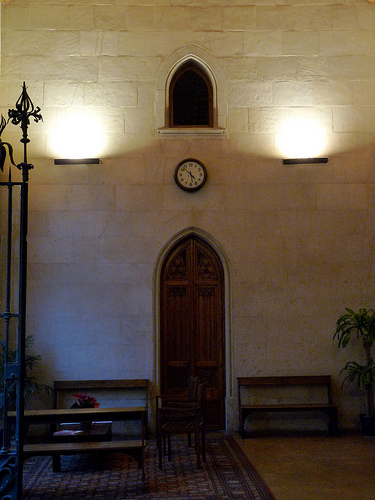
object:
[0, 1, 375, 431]
walls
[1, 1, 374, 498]
building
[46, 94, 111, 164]
light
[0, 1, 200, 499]
left side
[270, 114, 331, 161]
light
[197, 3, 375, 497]
right side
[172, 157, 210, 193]
clock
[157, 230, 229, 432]
door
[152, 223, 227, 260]
arch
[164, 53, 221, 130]
window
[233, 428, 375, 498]
floor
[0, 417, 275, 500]
carpet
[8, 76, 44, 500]
stick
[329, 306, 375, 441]
potted plant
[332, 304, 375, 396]
leaves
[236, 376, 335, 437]
bench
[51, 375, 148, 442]
bench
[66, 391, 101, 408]
flowers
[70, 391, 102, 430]
plant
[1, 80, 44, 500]
fencing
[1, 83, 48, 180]
design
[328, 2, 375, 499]
corner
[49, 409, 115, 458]
table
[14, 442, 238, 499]
designs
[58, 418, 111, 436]
magazines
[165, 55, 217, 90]
arched top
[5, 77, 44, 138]
sharp points